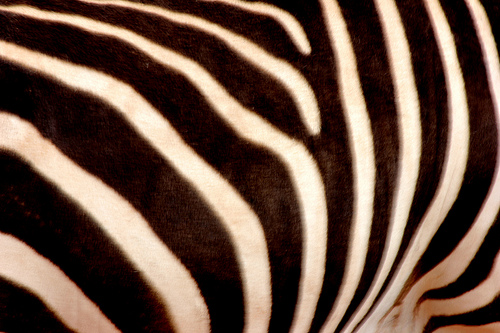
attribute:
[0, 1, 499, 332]
zebra — possible, striped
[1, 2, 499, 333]
pattern — monochromatic, striped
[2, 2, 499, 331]
stripes — white, horizontal, running, black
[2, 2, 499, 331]
animal — present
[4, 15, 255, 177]
hair — brown, dark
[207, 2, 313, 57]
stripe — curved, short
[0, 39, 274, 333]
stripe — long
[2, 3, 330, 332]
stripes — wider, white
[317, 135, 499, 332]
stripes — white, meeting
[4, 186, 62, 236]
spots — white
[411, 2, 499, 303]
stripe — black, white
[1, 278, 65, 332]
fur — brown, black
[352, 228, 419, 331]
gap — narrow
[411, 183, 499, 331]
part — white, black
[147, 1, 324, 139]
stripes — incomplete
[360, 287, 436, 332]
stripes — joined together